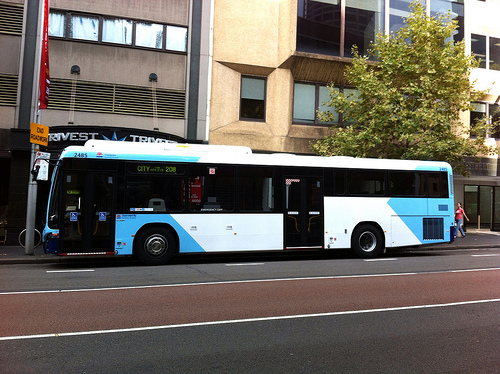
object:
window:
[96, 13, 136, 50]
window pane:
[161, 21, 192, 55]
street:
[0, 229, 499, 374]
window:
[48, 7, 72, 42]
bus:
[28, 137, 456, 265]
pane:
[64, 9, 104, 45]